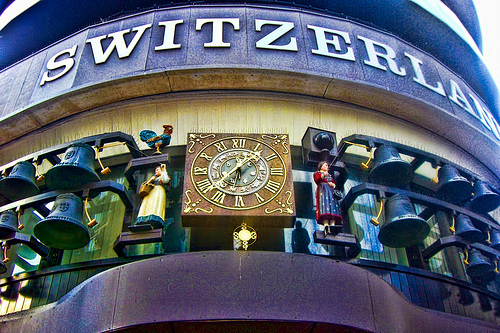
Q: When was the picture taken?
A: Daytime.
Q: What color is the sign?
A: Blue and white.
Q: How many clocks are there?
A: One.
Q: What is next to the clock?
A: The figurines.